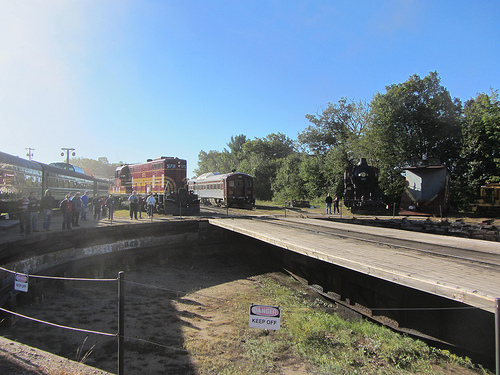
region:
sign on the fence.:
[244, 307, 285, 327]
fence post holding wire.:
[109, 269, 124, 371]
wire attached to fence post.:
[154, 287, 214, 297]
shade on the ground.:
[162, 255, 227, 279]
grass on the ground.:
[270, 288, 302, 323]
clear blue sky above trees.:
[298, 18, 356, 57]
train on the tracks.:
[202, 175, 252, 202]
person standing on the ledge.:
[60, 196, 73, 227]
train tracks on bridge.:
[288, 223, 414, 258]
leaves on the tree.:
[370, 117, 405, 140]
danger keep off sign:
[240, 299, 287, 334]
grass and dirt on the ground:
[297, 315, 410, 368]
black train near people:
[340, 152, 388, 214]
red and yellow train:
[115, 160, 187, 187]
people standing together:
[17, 192, 154, 224]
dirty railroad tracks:
[236, 212, 481, 298]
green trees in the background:
[241, 112, 331, 182]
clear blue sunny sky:
[110, 101, 240, 128]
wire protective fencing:
[37, 261, 187, 361]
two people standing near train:
[322, 194, 341, 218]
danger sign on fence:
[249, 302, 281, 329]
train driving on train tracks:
[193, 177, 250, 205]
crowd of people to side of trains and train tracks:
[14, 191, 165, 227]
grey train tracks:
[218, 207, 497, 312]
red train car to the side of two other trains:
[121, 163, 186, 193]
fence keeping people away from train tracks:
[39, 275, 229, 370]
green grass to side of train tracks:
[298, 313, 350, 345]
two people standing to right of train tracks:
[318, 187, 349, 216]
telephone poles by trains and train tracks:
[16, 141, 83, 162]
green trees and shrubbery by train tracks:
[305, 100, 495, 154]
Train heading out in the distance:
[188, 169, 257, 204]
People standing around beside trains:
[35, 191, 167, 229]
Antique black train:
[341, 155, 393, 215]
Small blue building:
[401, 163, 449, 213]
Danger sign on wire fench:
[246, 299, 282, 333]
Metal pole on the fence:
[114, 270, 126, 374]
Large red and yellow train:
[114, 158, 189, 215]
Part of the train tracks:
[271, 216, 296, 231]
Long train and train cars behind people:
[1, 152, 116, 208]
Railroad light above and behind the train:
[60, 146, 78, 163]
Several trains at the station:
[2, 141, 284, 244]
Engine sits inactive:
[321, 143, 416, 232]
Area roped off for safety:
[1, 233, 380, 374]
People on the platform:
[11, 176, 173, 242]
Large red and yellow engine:
[104, 152, 207, 222]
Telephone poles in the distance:
[17, 131, 96, 170]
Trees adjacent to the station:
[195, 61, 489, 218]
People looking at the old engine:
[315, 149, 367, 218]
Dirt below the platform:
[23, 228, 225, 373]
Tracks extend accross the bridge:
[216, 191, 498, 273]